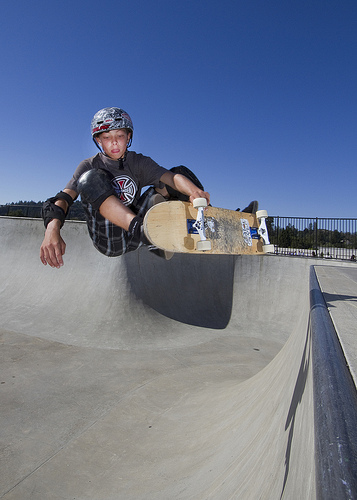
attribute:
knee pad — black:
[74, 164, 115, 208]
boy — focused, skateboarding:
[39, 106, 257, 268]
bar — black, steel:
[316, 332, 355, 496]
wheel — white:
[261, 240, 273, 255]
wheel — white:
[254, 208, 268, 221]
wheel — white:
[191, 197, 207, 208]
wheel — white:
[198, 239, 210, 252]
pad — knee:
[65, 165, 113, 213]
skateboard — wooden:
[132, 184, 298, 275]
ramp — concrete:
[1, 214, 356, 499]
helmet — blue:
[89, 106, 133, 146]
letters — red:
[90, 123, 109, 135]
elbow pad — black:
[38, 189, 71, 229]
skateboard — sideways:
[139, 198, 275, 265]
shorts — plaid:
[83, 183, 164, 258]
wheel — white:
[195, 238, 214, 252]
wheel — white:
[260, 244, 276, 258]